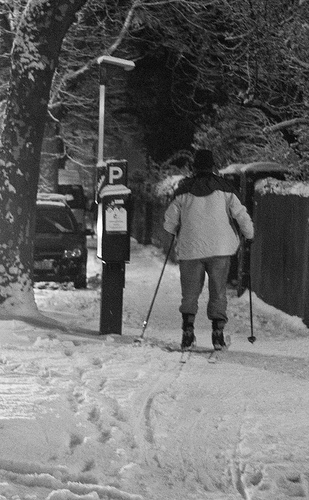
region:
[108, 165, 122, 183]
Large white P.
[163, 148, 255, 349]
A person skiing with ski poles.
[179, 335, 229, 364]
Two skis on a person.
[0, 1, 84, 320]
Large snowy tree trunk.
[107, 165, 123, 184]
A large white letter P.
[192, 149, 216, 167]
Black hat on a person skiing.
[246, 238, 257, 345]
The right side black ski pole.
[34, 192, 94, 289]
A black parked car facing the camera.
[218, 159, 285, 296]
Two porta potties to the right of a man.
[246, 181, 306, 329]
Dark fence to the right of a man.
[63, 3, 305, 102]
tree limbs with no leaves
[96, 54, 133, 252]
street light on pole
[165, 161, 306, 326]
snow on top of fence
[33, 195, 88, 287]
front of parked car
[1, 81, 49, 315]
snow on tree trunk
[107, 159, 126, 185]
white letter on sign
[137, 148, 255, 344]
back of person on skis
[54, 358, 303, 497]
footprints and ski marks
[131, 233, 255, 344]
two poles in hands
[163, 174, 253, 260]
back of winter coat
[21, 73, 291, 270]
black and white photo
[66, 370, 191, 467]
marks on the ground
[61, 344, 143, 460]
tracks in the snow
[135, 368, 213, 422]
white snow on the ground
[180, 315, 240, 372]
skis on the ground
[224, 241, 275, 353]
ski pole in person's hand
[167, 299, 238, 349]
two feet of the person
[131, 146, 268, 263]
person with back towards camera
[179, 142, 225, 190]
head of the person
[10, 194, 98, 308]
car in the snow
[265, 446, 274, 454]
part of the snow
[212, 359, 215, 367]
part of a board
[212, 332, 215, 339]
part of a skate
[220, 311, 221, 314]
part of a trouser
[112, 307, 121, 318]
edge of a wall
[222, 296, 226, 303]
part of a trouser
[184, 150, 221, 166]
Person wearing hat on head.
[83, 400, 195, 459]
Ground is covered in snow.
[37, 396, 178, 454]
Snow on ground is white.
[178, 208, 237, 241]
Person wearing white coat.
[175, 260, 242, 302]
Person wearing gray pants.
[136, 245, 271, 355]
Person holding 2 ski poles.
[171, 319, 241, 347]
Person wearing black boots.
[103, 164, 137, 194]
White letter P on sign.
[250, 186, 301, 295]
Large fence to the right of person.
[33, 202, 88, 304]
Car on road to left of person.